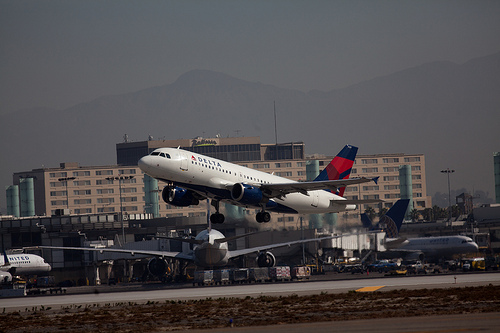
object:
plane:
[132, 145, 386, 222]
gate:
[41, 190, 489, 297]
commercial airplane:
[22, 226, 385, 270]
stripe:
[353, 281, 385, 296]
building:
[3, 210, 312, 292]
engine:
[230, 182, 264, 205]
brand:
[191, 154, 222, 169]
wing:
[259, 176, 372, 198]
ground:
[2, 287, 496, 318]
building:
[7, 152, 428, 235]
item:
[21, 244, 196, 261]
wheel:
[256, 251, 276, 268]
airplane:
[383, 234, 477, 254]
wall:
[263, 155, 425, 195]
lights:
[441, 168, 456, 206]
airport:
[1, 133, 498, 310]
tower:
[167, 140, 307, 162]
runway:
[2, 270, 498, 312]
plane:
[1, 252, 55, 296]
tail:
[308, 143, 362, 198]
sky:
[3, 0, 499, 220]